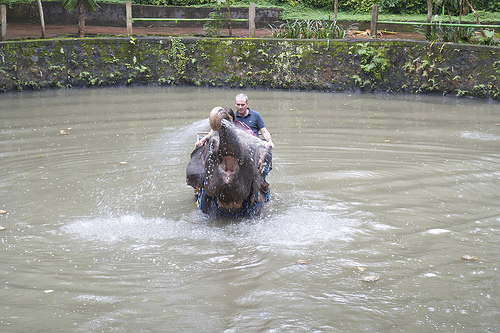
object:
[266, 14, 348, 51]
plant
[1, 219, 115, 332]
water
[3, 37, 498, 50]
edge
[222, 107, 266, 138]
shirt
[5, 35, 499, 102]
bank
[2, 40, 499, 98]
dirt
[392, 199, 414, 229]
ground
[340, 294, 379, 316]
ripples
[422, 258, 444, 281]
ripples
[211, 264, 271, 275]
ripples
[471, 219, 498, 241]
ripples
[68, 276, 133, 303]
ripples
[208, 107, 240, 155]
trunk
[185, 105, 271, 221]
elephant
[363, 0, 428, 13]
tree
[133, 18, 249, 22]
rope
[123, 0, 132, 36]
pole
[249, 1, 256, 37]
pole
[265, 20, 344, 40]
grass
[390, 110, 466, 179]
water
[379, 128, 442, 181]
ground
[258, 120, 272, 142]
arm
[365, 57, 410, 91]
ground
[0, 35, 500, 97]
short wall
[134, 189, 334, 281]
waves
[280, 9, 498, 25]
grass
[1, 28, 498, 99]
hill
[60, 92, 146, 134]
water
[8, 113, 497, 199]
ripples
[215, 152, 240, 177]
mouth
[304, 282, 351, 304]
ripples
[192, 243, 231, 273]
ripples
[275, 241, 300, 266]
ripples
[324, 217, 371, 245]
ripples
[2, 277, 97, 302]
ripples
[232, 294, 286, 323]
ripples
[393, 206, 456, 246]
ripples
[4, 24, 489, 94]
concrete edge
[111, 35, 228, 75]
grass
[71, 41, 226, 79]
plants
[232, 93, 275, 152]
man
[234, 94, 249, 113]
head